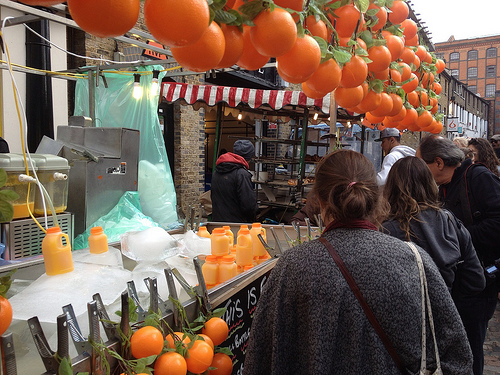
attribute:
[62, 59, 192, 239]
plastic bag — green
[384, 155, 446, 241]
hair — brown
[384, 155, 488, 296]
woman — grown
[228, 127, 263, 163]
hat — grey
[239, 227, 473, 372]
sweater — grey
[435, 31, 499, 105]
building — large, red, brick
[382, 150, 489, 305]
woman — brown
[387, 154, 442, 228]
hair — dark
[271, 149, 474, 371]
woman — grown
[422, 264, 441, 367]
straps — white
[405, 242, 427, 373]
straps — white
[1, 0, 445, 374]
stall — orange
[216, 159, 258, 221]
coat — black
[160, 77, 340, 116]
awning — red, white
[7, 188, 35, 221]
juice — orange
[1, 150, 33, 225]
container — large, plastic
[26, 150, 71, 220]
container — plastic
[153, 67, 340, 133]
canopy — white and red , stripe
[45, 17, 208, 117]
conditioner — gray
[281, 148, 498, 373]
people — looking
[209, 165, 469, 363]
woman — grown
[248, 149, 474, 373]
people — some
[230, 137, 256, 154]
hat — gray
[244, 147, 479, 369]
person — female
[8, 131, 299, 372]
truck —  side 